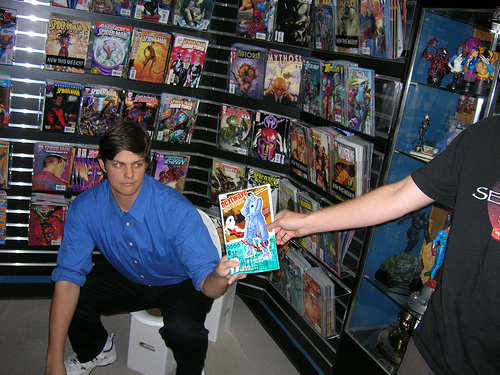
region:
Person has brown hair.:
[101, 127, 168, 177]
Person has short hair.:
[85, 139, 187, 166]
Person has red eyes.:
[110, 146, 155, 183]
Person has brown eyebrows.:
[105, 155, 189, 170]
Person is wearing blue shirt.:
[99, 205, 173, 255]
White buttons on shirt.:
[112, 197, 154, 337]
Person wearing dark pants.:
[88, 286, 178, 338]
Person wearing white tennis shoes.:
[66, 334, 90, 363]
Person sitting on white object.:
[103, 267, 200, 362]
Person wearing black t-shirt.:
[421, 229, 471, 309]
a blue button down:
[36, 169, 221, 304]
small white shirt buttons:
[117, 213, 154, 298]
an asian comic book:
[207, 175, 289, 290]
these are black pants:
[51, 250, 236, 370]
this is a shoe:
[44, 322, 144, 374]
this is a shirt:
[399, 115, 499, 367]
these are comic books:
[231, 105, 380, 177]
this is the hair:
[91, 114, 167, 174]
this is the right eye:
[108, 157, 129, 172]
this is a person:
[38, 122, 260, 374]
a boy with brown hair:
[83, 107, 163, 204]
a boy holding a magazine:
[73, 117, 289, 290]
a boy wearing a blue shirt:
[91, 114, 171, 274]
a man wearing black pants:
[71, 119, 229, 374]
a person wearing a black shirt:
[369, 85, 498, 339]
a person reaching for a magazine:
[213, 110, 488, 300]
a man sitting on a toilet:
[79, 125, 245, 373]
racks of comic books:
[201, 14, 408, 187]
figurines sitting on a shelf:
[388, 24, 495, 159]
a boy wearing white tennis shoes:
[67, 117, 190, 372]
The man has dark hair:
[83, 119, 167, 176]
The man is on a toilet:
[105, 276, 282, 372]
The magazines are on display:
[220, 44, 405, 265]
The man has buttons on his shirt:
[68, 180, 181, 318]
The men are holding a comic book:
[200, 176, 297, 279]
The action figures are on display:
[346, 147, 488, 354]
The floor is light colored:
[229, 327, 278, 373]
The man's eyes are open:
[95, 157, 150, 192]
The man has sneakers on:
[46, 312, 124, 372]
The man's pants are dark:
[106, 260, 276, 373]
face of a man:
[115, 163, 142, 185]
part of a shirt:
[99, 223, 111, 243]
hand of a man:
[316, 215, 345, 217]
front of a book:
[238, 204, 258, 244]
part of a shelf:
[282, 282, 336, 328]